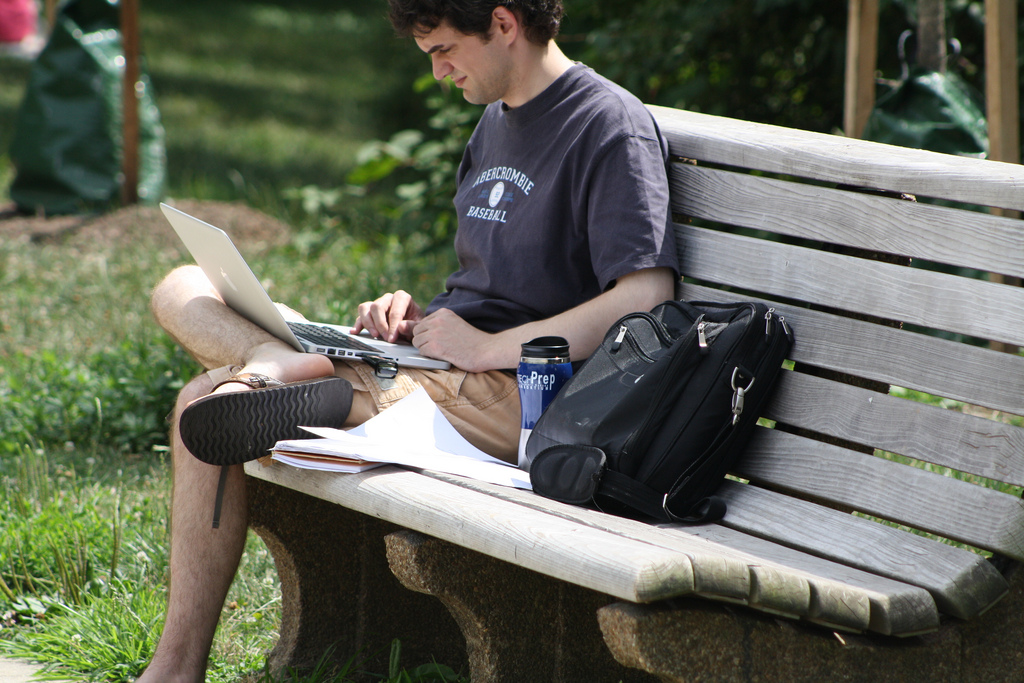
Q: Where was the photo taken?
A: Near a park bench.